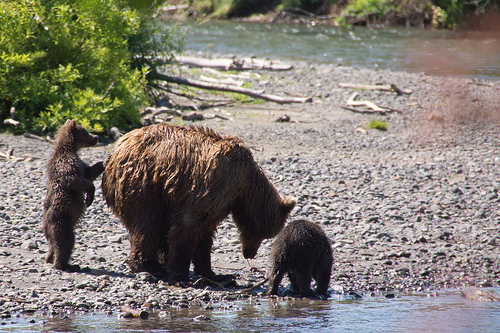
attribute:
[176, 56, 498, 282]
dirt — brown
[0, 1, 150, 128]
bush — green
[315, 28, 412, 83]
water — green